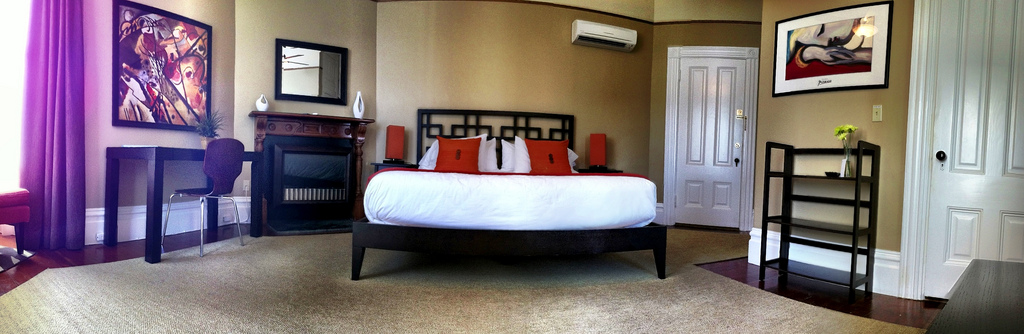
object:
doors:
[666, 5, 1024, 303]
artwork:
[772, 4, 893, 96]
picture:
[112, 2, 210, 133]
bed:
[351, 108, 671, 282]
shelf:
[758, 140, 879, 296]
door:
[659, 45, 758, 229]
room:
[0, 0, 1019, 332]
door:
[896, 0, 1020, 304]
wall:
[750, 3, 915, 252]